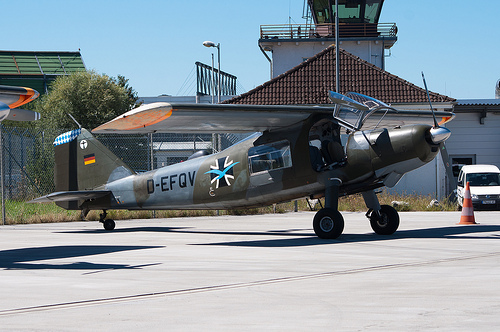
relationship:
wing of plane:
[40, 185, 106, 215] [58, 87, 460, 244]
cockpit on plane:
[308, 121, 349, 161] [58, 87, 460, 244]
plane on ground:
[58, 87, 460, 244] [49, 217, 454, 314]